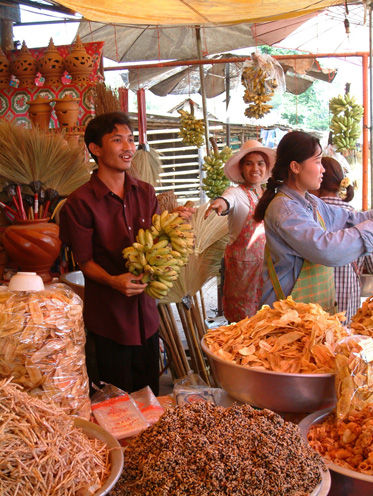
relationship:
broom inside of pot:
[2, 118, 93, 224] [2, 222, 65, 287]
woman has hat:
[204, 139, 278, 323] [223, 139, 275, 183]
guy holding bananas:
[54, 110, 202, 407] [122, 207, 200, 300]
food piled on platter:
[111, 393, 331, 495] [302, 459, 335, 495]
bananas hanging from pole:
[242, 55, 282, 125] [106, 49, 371, 76]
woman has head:
[204, 139, 278, 323] [238, 154, 273, 189]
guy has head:
[54, 110, 202, 407] [79, 109, 144, 174]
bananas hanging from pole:
[122, 207, 200, 300] [106, 49, 371, 76]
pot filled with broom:
[2, 222, 65, 287] [2, 118, 93, 224]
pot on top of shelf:
[62, 33, 94, 90] [2, 38, 106, 175]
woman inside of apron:
[204, 139, 278, 323] [219, 186, 268, 323]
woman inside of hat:
[204, 139, 278, 323] [223, 139, 275, 183]